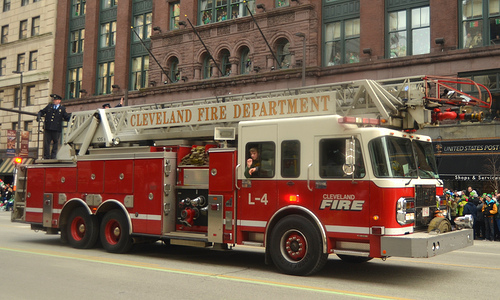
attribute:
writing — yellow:
[129, 93, 329, 126]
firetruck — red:
[18, 76, 481, 277]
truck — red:
[9, 71, 494, 278]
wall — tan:
[425, 126, 499, 139]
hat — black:
[48, 92, 63, 103]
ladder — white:
[57, 77, 494, 146]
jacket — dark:
[33, 97, 73, 129]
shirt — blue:
[52, 103, 60, 110]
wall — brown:
[52, 1, 499, 194]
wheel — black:
[259, 209, 329, 277]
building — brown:
[1, 0, 499, 198]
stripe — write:
[26, 207, 413, 237]